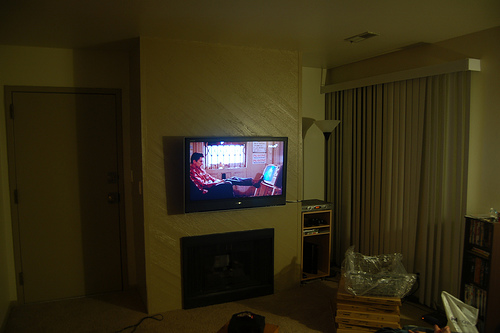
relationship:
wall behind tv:
[136, 56, 374, 304] [176, 127, 334, 207]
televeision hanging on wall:
[166, 134, 288, 211] [139, 40, 378, 130]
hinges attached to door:
[4, 178, 31, 217] [10, 70, 134, 325]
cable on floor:
[126, 311, 159, 326] [148, 319, 175, 329]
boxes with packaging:
[333, 263, 404, 331] [335, 239, 419, 306]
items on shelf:
[463, 201, 498, 324] [457, 205, 499, 331]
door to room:
[12, 85, 126, 305] [26, 46, 476, 323]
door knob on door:
[106, 184, 126, 206] [6, 80, 151, 306]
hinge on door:
[6, 103, 15, 121] [12, 85, 126, 305]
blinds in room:
[327, 58, 484, 296] [1, 2, 493, 332]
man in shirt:
[189, 152, 265, 195] [190, 162, 217, 192]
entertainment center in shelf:
[300, 209, 335, 283] [302, 222, 330, 230]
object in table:
[230, 310, 265, 330] [216, 319, 275, 331]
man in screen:
[189, 150, 266, 194] [185, 140, 285, 204]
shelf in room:
[301, 207, 331, 282] [1, 2, 493, 332]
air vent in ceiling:
[341, 28, 391, 60] [65, 8, 400, 46]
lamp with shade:
[312, 115, 339, 199] [312, 116, 342, 135]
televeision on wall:
[166, 134, 288, 211] [144, 36, 308, 307]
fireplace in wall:
[180, 223, 275, 306] [144, 36, 308, 307]